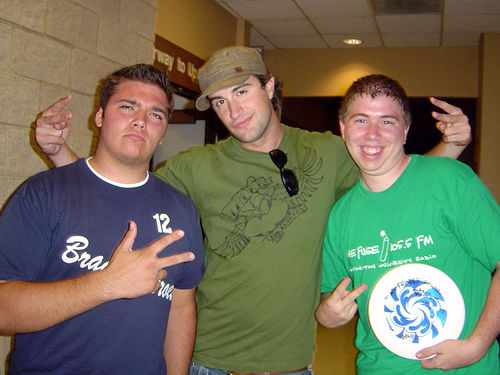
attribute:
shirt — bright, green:
[299, 155, 497, 365]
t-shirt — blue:
[0, 158, 208, 373]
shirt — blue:
[15, 135, 277, 362]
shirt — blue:
[59, 175, 148, 212]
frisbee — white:
[368, 260, 466, 363]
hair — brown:
[96, 59, 191, 109]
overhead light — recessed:
[341, 35, 365, 46]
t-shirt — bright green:
[321, 152, 498, 370]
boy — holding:
[33, 45, 478, 372]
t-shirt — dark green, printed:
[192, 137, 314, 355]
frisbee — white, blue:
[363, 260, 471, 362]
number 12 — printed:
[147, 209, 179, 237]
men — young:
[11, 68, 499, 367]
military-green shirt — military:
[158, 126, 355, 369]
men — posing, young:
[318, 69, 498, 364]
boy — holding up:
[313, 73, 498, 373]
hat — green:
[195, 46, 265, 110]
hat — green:
[190, 45, 272, 112]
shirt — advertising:
[316, 151, 498, 372]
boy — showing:
[4, 57, 209, 373]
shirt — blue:
[5, 153, 233, 373]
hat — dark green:
[168, 49, 260, 96]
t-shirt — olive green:
[168, 123, 351, 373]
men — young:
[0, 45, 497, 373]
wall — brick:
[0, 1, 156, 372]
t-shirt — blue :
[4, 158, 225, 371]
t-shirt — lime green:
[316, 148, 479, 373]